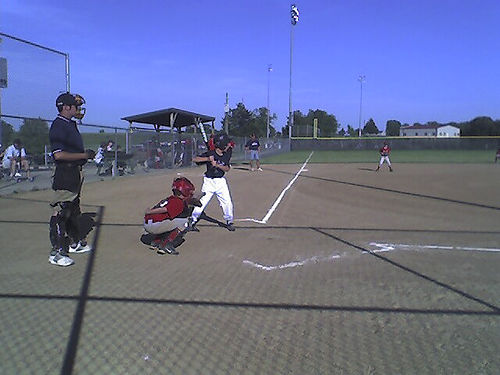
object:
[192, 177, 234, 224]
pants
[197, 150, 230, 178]
shirt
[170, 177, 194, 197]
helmet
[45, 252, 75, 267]
shoe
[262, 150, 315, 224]
line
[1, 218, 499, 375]
shadow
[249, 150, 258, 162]
shorts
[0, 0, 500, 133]
sky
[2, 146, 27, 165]
shirt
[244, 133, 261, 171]
person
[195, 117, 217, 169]
bat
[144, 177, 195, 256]
boy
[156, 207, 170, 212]
hand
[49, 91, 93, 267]
umpire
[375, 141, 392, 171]
player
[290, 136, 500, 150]
fence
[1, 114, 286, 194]
fence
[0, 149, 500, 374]
ground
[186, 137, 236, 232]
boy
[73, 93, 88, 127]
face mask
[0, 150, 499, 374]
field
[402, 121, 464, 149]
buildings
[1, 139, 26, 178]
people